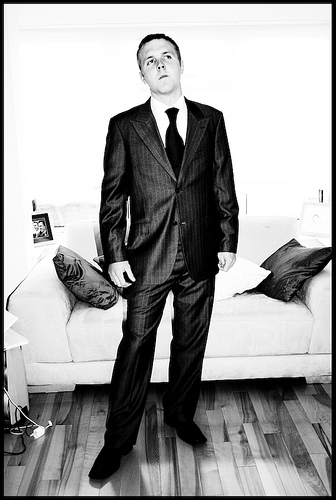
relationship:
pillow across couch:
[260, 235, 330, 301] [8, 197, 330, 393]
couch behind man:
[8, 197, 330, 393] [86, 32, 243, 481]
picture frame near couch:
[30, 211, 53, 242] [8, 197, 330, 393]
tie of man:
[163, 105, 187, 175] [86, 32, 243, 481]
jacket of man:
[99, 94, 245, 286] [86, 32, 243, 481]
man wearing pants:
[86, 32, 243, 481] [101, 239, 220, 450]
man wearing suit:
[86, 32, 243, 481] [99, 94, 243, 449]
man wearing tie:
[86, 32, 243, 481] [163, 105, 187, 175]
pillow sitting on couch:
[260, 235, 330, 301] [8, 197, 330, 393]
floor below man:
[4, 376, 334, 498] [86, 32, 243, 481]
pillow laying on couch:
[260, 235, 330, 301] [8, 197, 330, 393]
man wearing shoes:
[86, 32, 243, 481] [85, 406, 209, 483]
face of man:
[144, 51, 177, 85] [86, 32, 243, 481]